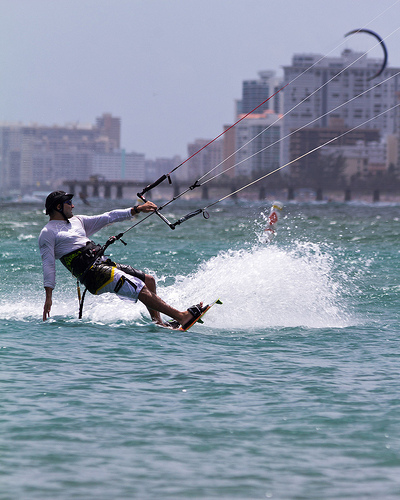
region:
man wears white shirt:
[42, 233, 68, 242]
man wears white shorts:
[123, 285, 133, 297]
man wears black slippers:
[188, 295, 212, 331]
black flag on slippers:
[212, 292, 227, 312]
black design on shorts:
[114, 276, 130, 286]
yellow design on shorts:
[109, 269, 115, 277]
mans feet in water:
[151, 285, 227, 341]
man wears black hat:
[41, 187, 67, 204]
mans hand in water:
[32, 307, 65, 335]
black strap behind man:
[75, 285, 90, 319]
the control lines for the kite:
[103, 3, 399, 247]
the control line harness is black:
[59, 231, 120, 281]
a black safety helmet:
[43, 189, 73, 220]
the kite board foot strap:
[187, 302, 202, 319]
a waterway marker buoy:
[258, 195, 283, 245]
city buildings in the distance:
[0, 113, 147, 193]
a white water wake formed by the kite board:
[216, 240, 368, 329]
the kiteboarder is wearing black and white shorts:
[86, 257, 143, 301]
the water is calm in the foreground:
[0, 333, 398, 498]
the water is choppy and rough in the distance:
[0, 200, 43, 306]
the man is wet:
[55, 194, 258, 379]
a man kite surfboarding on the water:
[38, 2, 398, 332]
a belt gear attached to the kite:
[58, 239, 112, 280]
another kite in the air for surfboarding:
[342, 29, 398, 83]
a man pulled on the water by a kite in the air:
[39, 188, 223, 332]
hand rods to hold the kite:
[137, 192, 173, 229]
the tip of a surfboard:
[179, 298, 225, 332]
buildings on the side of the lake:
[1, 47, 399, 188]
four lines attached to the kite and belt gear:
[167, 4, 397, 204]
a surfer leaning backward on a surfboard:
[38, 171, 223, 332]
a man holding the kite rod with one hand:
[38, 190, 224, 335]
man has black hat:
[36, 187, 81, 225]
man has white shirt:
[36, 206, 150, 279]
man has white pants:
[82, 262, 164, 292]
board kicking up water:
[159, 223, 347, 342]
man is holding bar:
[119, 166, 191, 239]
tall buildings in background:
[235, 64, 375, 165]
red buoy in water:
[264, 200, 280, 237]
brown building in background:
[1, 103, 138, 202]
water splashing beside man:
[197, 249, 363, 341]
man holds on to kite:
[83, 178, 181, 234]